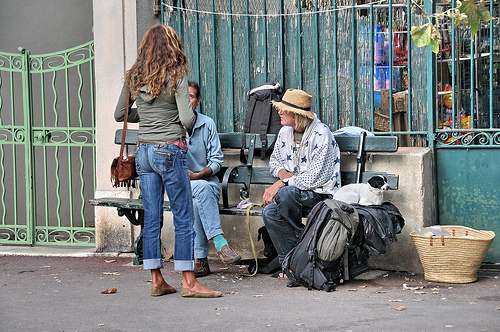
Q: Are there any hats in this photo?
A: Yes, there is a hat.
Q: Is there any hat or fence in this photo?
A: Yes, there is a hat.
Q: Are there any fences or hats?
A: Yes, there is a hat.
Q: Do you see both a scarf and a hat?
A: No, there is a hat but no scarves.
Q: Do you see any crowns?
A: No, there are no crowns.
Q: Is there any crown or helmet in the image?
A: No, there are no crowns or helmets.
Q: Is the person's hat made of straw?
A: Yes, the hat is made of straw.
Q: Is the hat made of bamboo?
A: No, the hat is made of straw.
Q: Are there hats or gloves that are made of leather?
A: No, there is a hat but it is made of straw.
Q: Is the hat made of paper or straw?
A: The hat is made of straw.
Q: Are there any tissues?
A: No, there are no tissues.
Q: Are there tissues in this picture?
A: No, there are no tissues.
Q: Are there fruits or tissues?
A: No, there are no tissues or fruits.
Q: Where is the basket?
A: The basket is on the side walk.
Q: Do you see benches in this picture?
A: Yes, there is a bench.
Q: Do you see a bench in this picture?
A: Yes, there is a bench.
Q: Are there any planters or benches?
A: Yes, there is a bench.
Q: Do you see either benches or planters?
A: Yes, there is a bench.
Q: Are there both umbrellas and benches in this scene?
A: No, there is a bench but no umbrellas.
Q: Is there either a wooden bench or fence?
A: Yes, there is a wood bench.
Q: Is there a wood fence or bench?
A: Yes, there is a wood bench.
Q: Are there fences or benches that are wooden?
A: Yes, the bench is wooden.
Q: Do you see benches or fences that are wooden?
A: Yes, the bench is wooden.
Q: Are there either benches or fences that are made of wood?
A: Yes, the bench is made of wood.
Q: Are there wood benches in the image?
A: Yes, there is a wood bench.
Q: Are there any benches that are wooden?
A: Yes, there is a bench that is wooden.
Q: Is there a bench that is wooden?
A: Yes, there is a bench that is wooden.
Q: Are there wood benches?
A: Yes, there is a bench that is made of wood.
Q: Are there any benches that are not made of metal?
A: Yes, there is a bench that is made of wood.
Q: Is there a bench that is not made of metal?
A: Yes, there is a bench that is made of wood.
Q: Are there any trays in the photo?
A: No, there are no trays.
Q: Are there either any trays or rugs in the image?
A: No, there are no trays or rugs.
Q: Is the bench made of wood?
A: Yes, the bench is made of wood.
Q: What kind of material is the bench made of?
A: The bench is made of wood.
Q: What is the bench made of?
A: The bench is made of wood.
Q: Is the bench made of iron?
A: No, the bench is made of wood.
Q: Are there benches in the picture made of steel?
A: No, there is a bench but it is made of wood.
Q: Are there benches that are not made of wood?
A: No, there is a bench but it is made of wood.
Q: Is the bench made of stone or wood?
A: The bench is made of wood.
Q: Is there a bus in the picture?
A: No, there are no buses.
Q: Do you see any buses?
A: No, there are no buses.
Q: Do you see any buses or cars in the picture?
A: No, there are no buses or cars.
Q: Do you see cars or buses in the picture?
A: No, there are no buses or cars.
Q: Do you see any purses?
A: Yes, there is a purse.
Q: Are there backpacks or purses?
A: Yes, there is a purse.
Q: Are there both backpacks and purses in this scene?
A: Yes, there are both a purse and a backpack.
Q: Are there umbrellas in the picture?
A: No, there are no umbrellas.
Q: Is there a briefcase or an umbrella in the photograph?
A: No, there are no umbrellas or briefcases.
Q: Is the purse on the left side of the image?
A: Yes, the purse is on the left of the image.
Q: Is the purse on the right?
A: No, the purse is on the left of the image.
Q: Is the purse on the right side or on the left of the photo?
A: The purse is on the left of the image.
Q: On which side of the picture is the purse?
A: The purse is on the left of the image.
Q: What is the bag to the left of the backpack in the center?
A: The bag is a purse.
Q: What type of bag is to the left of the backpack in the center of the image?
A: The bag is a purse.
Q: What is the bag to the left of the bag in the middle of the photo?
A: The bag is a purse.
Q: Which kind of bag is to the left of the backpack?
A: The bag is a purse.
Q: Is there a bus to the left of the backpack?
A: No, there is a purse to the left of the backpack.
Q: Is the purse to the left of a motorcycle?
A: No, the purse is to the left of the backpack.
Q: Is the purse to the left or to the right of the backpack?
A: The purse is to the left of the backpack.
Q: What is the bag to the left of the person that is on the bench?
A: The bag is a purse.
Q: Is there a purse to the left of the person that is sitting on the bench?
A: Yes, there is a purse to the left of the person.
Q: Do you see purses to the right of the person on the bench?
A: No, the purse is to the left of the person.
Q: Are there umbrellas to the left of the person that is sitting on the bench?
A: No, there is a purse to the left of the person.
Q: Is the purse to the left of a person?
A: Yes, the purse is to the left of a person.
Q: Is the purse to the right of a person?
A: No, the purse is to the left of a person.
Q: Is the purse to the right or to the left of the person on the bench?
A: The purse is to the left of the person.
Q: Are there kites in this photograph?
A: No, there are no kites.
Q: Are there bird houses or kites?
A: No, there are no kites or bird houses.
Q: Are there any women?
A: Yes, there is a woman.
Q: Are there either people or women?
A: Yes, there is a woman.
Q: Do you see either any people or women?
A: Yes, there is a woman.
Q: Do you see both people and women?
A: Yes, there are both a woman and a person.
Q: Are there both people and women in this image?
A: Yes, there are both a woman and a person.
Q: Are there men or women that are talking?
A: Yes, the woman is talking.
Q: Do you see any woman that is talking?
A: Yes, there is a woman that is talking.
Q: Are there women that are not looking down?
A: Yes, there is a woman that is talking.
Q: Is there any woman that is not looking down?
A: Yes, there is a woman that is talking.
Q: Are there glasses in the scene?
A: No, there are no glasses.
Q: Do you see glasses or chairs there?
A: No, there are no glasses or chairs.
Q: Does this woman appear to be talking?
A: Yes, the woman is talking.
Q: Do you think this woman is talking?
A: Yes, the woman is talking.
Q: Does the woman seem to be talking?
A: Yes, the woman is talking.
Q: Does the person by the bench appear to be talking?
A: Yes, the woman is talking.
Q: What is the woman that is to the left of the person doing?
A: The woman is talking.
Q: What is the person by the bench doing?
A: The woman is talking.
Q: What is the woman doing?
A: The woman is talking.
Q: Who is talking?
A: The woman is talking.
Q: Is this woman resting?
A: No, the woman is talking.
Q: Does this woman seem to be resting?
A: No, the woman is talking.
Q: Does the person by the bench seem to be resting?
A: No, the woman is talking.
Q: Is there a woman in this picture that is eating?
A: No, there is a woman but she is talking.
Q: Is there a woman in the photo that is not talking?
A: No, there is a woman but she is talking.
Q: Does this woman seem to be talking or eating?
A: The woman is talking.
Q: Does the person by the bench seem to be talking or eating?
A: The woman is talking.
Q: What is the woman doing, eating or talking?
A: The woman is talking.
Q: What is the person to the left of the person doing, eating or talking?
A: The woman is talking.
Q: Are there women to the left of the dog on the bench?
A: Yes, there is a woman to the left of the dog.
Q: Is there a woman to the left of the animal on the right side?
A: Yes, there is a woman to the left of the dog.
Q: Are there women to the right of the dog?
A: No, the woman is to the left of the dog.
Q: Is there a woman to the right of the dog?
A: No, the woman is to the left of the dog.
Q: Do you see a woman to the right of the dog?
A: No, the woman is to the left of the dog.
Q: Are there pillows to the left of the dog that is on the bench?
A: No, there is a woman to the left of the dog.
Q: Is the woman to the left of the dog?
A: Yes, the woman is to the left of the dog.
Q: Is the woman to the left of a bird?
A: No, the woman is to the left of the dog.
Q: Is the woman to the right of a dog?
A: No, the woman is to the left of a dog.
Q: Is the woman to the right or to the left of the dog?
A: The woman is to the left of the dog.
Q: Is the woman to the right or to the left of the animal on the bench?
A: The woman is to the left of the dog.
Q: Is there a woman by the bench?
A: Yes, there is a woman by the bench.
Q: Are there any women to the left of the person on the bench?
A: Yes, there is a woman to the left of the person.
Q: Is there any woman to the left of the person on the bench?
A: Yes, there is a woman to the left of the person.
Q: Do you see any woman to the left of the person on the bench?
A: Yes, there is a woman to the left of the person.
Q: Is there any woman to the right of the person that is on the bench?
A: No, the woman is to the left of the person.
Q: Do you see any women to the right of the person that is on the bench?
A: No, the woman is to the left of the person.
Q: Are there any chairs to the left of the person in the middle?
A: No, there is a woman to the left of the person.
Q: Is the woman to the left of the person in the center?
A: Yes, the woman is to the left of the person.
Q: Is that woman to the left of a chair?
A: No, the woman is to the left of the person.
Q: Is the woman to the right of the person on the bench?
A: No, the woman is to the left of the person.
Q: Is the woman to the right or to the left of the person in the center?
A: The woman is to the left of the person.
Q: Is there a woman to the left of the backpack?
A: Yes, there is a woman to the left of the backpack.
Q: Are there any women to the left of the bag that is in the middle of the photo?
A: Yes, there is a woman to the left of the backpack.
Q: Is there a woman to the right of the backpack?
A: No, the woman is to the left of the backpack.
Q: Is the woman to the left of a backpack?
A: Yes, the woman is to the left of a backpack.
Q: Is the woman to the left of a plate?
A: No, the woman is to the left of a backpack.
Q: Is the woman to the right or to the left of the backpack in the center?
A: The woman is to the left of the backpack.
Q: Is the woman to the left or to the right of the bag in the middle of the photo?
A: The woman is to the left of the backpack.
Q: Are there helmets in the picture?
A: No, there are no helmets.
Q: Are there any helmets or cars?
A: No, there are no helmets or cars.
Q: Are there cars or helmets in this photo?
A: No, there are no helmets or cars.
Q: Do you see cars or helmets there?
A: No, there are no helmets or cars.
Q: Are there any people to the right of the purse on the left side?
A: Yes, there is a person to the right of the purse.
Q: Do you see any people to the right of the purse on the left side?
A: Yes, there is a person to the right of the purse.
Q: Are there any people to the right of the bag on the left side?
A: Yes, there is a person to the right of the purse.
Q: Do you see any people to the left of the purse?
A: No, the person is to the right of the purse.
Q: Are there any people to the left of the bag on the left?
A: No, the person is to the right of the purse.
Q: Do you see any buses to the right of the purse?
A: No, there is a person to the right of the purse.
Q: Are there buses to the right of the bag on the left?
A: No, there is a person to the right of the purse.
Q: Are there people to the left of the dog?
A: Yes, there is a person to the left of the dog.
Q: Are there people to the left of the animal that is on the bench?
A: Yes, there is a person to the left of the dog.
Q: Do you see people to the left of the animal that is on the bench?
A: Yes, there is a person to the left of the dog.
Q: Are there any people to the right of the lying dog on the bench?
A: No, the person is to the left of the dog.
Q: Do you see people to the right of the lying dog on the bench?
A: No, the person is to the left of the dog.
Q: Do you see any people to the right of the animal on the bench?
A: No, the person is to the left of the dog.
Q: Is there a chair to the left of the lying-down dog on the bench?
A: No, there is a person to the left of the dog.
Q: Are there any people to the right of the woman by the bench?
A: Yes, there is a person to the right of the woman.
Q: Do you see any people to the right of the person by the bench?
A: Yes, there is a person to the right of the woman.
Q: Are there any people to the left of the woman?
A: No, the person is to the right of the woman.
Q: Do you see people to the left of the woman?
A: No, the person is to the right of the woman.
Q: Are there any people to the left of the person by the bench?
A: No, the person is to the right of the woman.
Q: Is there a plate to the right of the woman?
A: No, there is a person to the right of the woman.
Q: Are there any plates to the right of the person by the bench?
A: No, there is a person to the right of the woman.